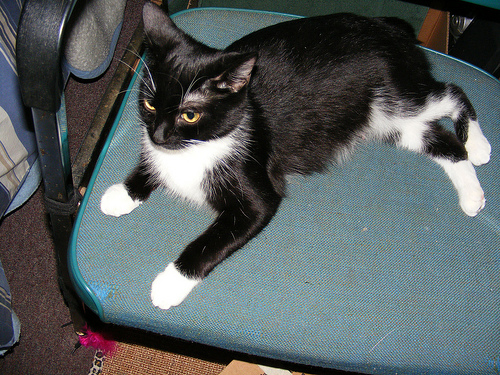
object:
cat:
[98, 14, 491, 309]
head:
[137, 1, 256, 154]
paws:
[149, 264, 199, 309]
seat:
[16, 0, 500, 375]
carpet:
[0, 0, 143, 373]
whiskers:
[113, 49, 155, 107]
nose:
[150, 124, 170, 149]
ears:
[210, 50, 260, 90]